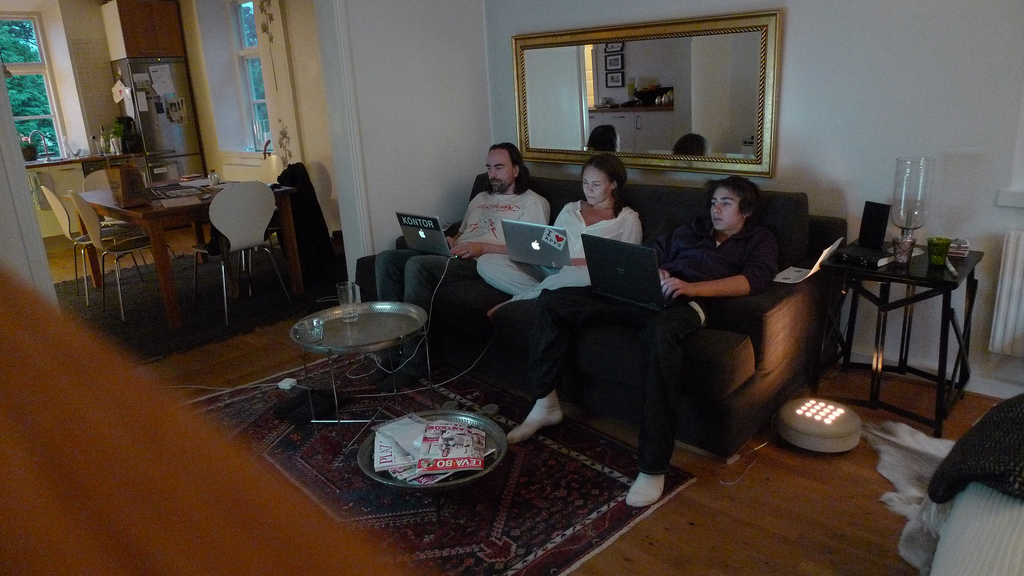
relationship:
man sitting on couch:
[370, 139, 554, 390] [352, 167, 854, 468]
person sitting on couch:
[477, 152, 643, 321] [352, 167, 854, 468]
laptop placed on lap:
[499, 214, 575, 273] [484, 247, 591, 282]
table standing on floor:
[285, 296, 437, 428] [47, 223, 985, 573]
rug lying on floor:
[173, 338, 698, 572] [47, 223, 985, 573]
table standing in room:
[817, 236, 984, 438] [4, 3, 992, 568]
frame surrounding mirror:
[510, 5, 787, 183] [518, 31, 763, 163]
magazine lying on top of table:
[413, 418, 485, 473] [352, 405, 513, 542]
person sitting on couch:
[473, 147, 649, 327] [352, 167, 854, 468]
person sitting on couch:
[499, 171, 785, 513] [352, 167, 854, 468]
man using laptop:
[369, 142, 551, 392] [391, 208, 465, 256]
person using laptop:
[473, 147, 649, 327] [497, 217, 582, 269]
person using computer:
[499, 171, 785, 513] [581, 233, 705, 312]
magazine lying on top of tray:
[416, 422, 486, 474] [350, 404, 513, 493]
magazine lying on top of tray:
[367, 431, 419, 473] [350, 404, 513, 493]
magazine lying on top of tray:
[384, 418, 426, 460] [350, 404, 513, 493]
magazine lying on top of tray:
[389, 461, 429, 483] [350, 404, 513, 493]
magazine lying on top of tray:
[410, 467, 454, 491] [350, 404, 513, 493]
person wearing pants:
[507, 175, 780, 507] [521, 282, 710, 475]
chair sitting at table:
[68, 189, 197, 323] [73, 178, 316, 336]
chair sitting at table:
[37, 182, 139, 312] [73, 178, 316, 336]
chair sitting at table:
[191, 181, 294, 327] [73, 178, 316, 336]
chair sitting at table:
[76, 163, 176, 287] [73, 178, 316, 336]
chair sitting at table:
[240, 154, 321, 304] [73, 178, 316, 336]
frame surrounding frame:
[512, 7, 784, 178] [512, 7, 784, 178]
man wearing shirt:
[370, 139, 554, 390] [454, 184, 552, 260]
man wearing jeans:
[370, 139, 554, 390] [370, 238, 483, 368]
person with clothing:
[477, 152, 643, 321] [532, 184, 675, 336]